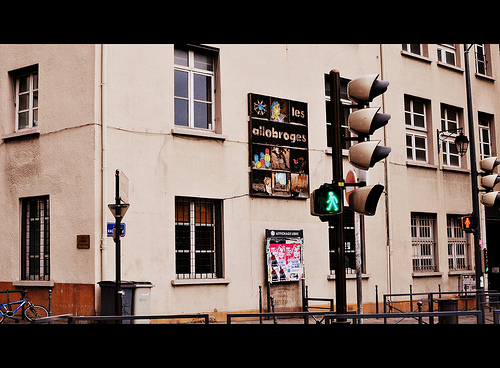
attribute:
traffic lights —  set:
[308, 60, 393, 322]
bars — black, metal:
[173, 197, 226, 277]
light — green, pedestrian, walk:
[323, 188, 340, 211]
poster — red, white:
[269, 241, 307, 286]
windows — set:
[7, 66, 39, 130]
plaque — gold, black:
[74, 232, 90, 249]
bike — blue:
[0, 285, 49, 321]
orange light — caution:
[457, 210, 482, 235]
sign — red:
[444, 200, 484, 242]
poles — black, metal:
[250, 282, 488, 324]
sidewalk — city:
[203, 309, 486, 331]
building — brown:
[3, 45, 497, 307]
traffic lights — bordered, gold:
[476, 148, 499, 196]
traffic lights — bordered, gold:
[343, 70, 385, 227]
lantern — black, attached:
[434, 122, 480, 162]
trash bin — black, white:
[127, 279, 156, 324]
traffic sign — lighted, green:
[311, 171, 347, 226]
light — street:
[307, 182, 344, 219]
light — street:
[345, 69, 392, 105]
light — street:
[344, 105, 391, 136]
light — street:
[348, 137, 391, 169]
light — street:
[344, 182, 386, 217]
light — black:
[449, 123, 470, 156]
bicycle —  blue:
[2, 285, 52, 322]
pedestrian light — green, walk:
[320, 186, 342, 215]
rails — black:
[66, 288, 499, 325]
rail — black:
[66, 290, 499, 327]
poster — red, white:
[261, 237, 308, 285]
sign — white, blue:
[106, 220, 129, 239]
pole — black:
[328, 69, 348, 322]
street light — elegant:
[455, 132, 470, 155]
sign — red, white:
[266, 236, 305, 285]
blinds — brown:
[174, 199, 215, 225]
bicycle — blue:
[0, 290, 48, 325]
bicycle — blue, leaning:
[0, 287, 50, 322]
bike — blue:
[0, 289, 49, 325]